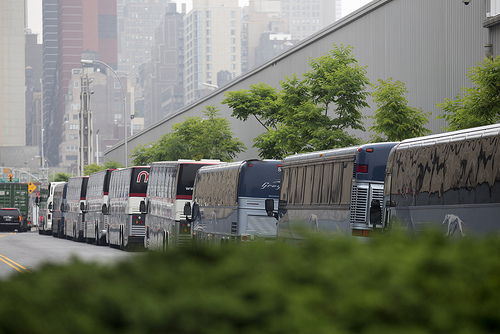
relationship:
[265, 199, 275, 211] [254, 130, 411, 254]
mirror on bus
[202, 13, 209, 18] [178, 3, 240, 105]
window on building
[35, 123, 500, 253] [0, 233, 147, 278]
bus parked on street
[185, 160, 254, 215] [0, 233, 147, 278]
bus parked on street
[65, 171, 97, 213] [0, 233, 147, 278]
bus parked on street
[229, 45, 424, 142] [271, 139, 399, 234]
green trees beside bus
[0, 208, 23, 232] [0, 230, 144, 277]
car on road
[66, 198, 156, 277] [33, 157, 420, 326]
line on ground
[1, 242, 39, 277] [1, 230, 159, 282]
line on ground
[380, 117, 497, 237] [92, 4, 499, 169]
bus next to building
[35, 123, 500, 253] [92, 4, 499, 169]
bus next to building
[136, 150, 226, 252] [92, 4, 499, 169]
bus next to building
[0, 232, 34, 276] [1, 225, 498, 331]
line on ground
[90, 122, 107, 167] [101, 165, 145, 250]
street light near bus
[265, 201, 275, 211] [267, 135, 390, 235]
mirror on bus